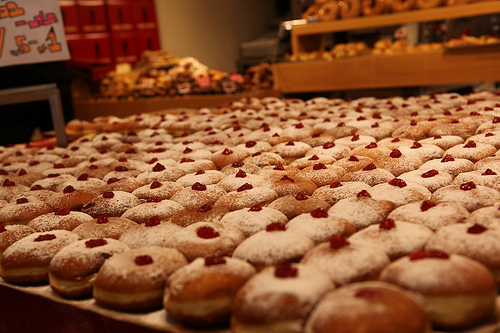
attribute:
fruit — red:
[130, 249, 159, 270]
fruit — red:
[81, 237, 110, 253]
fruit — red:
[34, 227, 60, 247]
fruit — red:
[229, 93, 399, 142]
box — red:
[66, 2, 153, 70]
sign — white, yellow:
[0, 3, 76, 70]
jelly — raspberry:
[276, 262, 303, 283]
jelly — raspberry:
[272, 260, 297, 272]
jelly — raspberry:
[280, 267, 290, 278]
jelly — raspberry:
[271, 264, 298, 283]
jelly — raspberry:
[275, 262, 294, 280]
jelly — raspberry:
[277, 258, 296, 276]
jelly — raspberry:
[267, 262, 295, 279]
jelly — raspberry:
[196, 248, 225, 268]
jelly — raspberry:
[280, 262, 292, 278]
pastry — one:
[244, 293, 294, 320]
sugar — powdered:
[315, 259, 355, 273]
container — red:
[79, 22, 126, 49]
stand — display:
[305, 27, 449, 71]